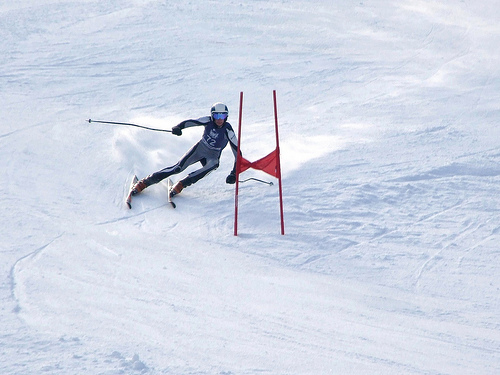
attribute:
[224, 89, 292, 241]
flag — red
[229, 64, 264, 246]
pole — red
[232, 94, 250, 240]
pole — red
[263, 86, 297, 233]
pole — red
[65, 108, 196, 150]
pole — ski pole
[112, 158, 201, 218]
skier — male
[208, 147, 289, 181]
flag — red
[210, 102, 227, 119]
helmet — white, blue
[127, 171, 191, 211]
shoes — brown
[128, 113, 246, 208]
snowsuit — black, grey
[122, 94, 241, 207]
skier — tilted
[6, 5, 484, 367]
slope — snowy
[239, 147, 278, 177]
flag — red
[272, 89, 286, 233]
post — red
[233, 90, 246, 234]
post — red